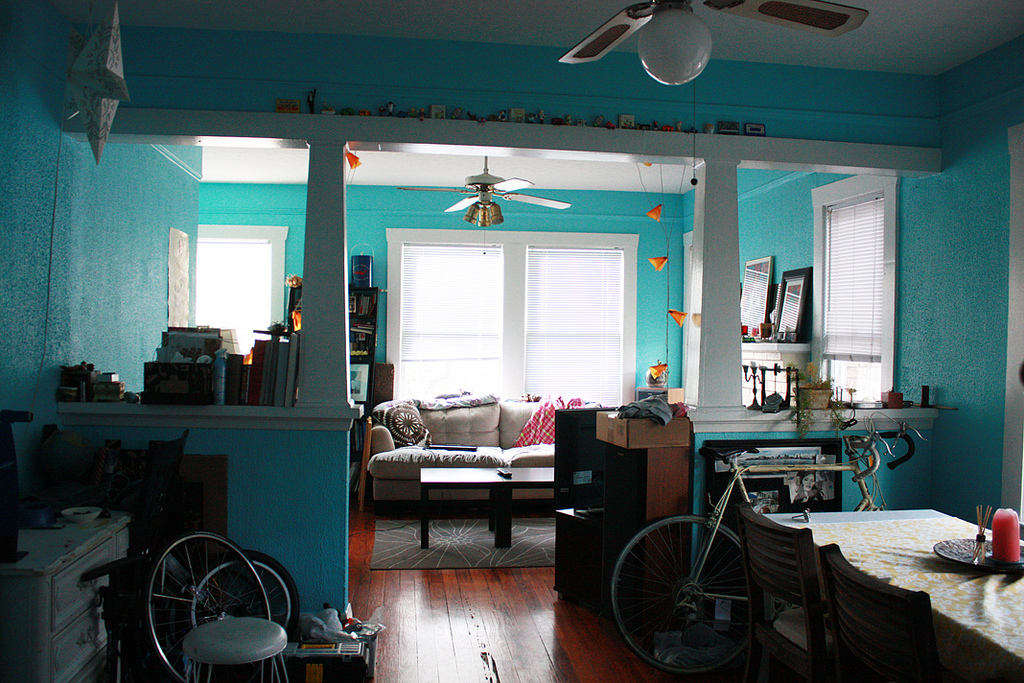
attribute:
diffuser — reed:
[954, 504, 991, 569]